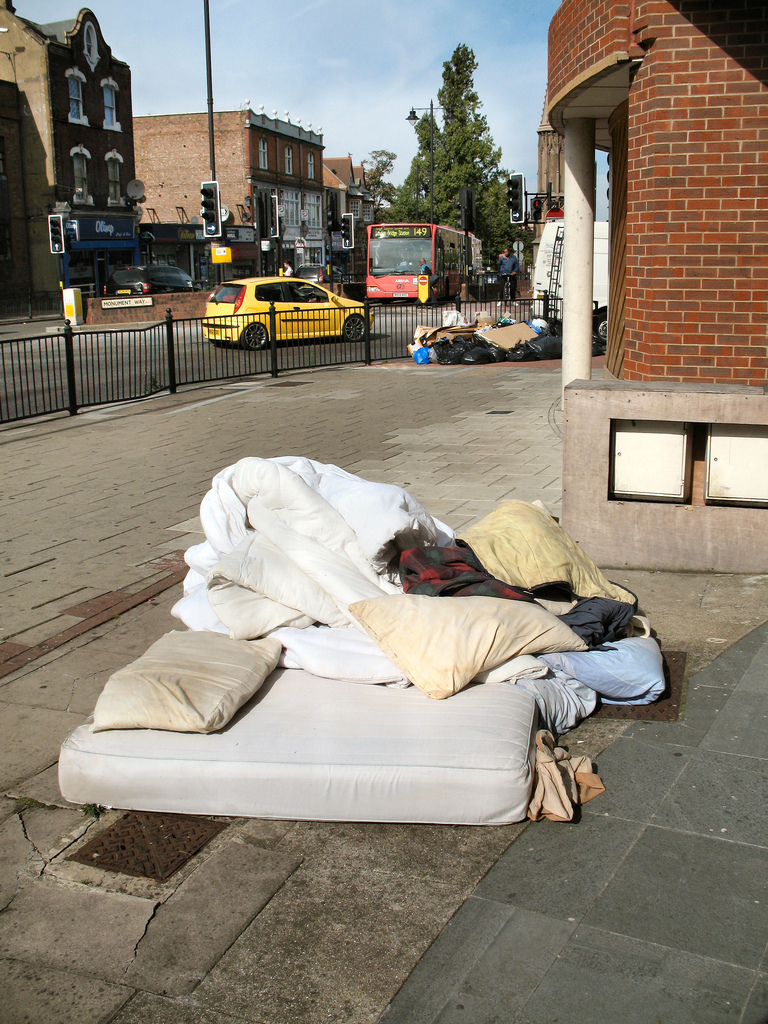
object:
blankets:
[190, 443, 401, 586]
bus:
[359, 208, 465, 328]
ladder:
[542, 224, 572, 330]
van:
[507, 191, 611, 326]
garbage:
[531, 309, 550, 340]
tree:
[444, 32, 514, 276]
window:
[65, 60, 87, 128]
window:
[85, 20, 99, 64]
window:
[71, 140, 90, 208]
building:
[0, 8, 167, 320]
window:
[258, 126, 268, 181]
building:
[134, 99, 325, 274]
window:
[307, 150, 316, 185]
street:
[8, 245, 483, 402]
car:
[190, 271, 396, 358]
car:
[113, 254, 208, 295]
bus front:
[367, 213, 437, 299]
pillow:
[77, 621, 287, 742]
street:
[0, 400, 758, 1022]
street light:
[194, 172, 227, 251]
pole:
[198, 5, 228, 180]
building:
[536, 5, 765, 407]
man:
[492, 243, 524, 311]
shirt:
[480, 271, 496, 290]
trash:
[483, 315, 535, 351]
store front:
[39, 14, 146, 318]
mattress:
[31, 600, 592, 847]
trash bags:
[444, 311, 472, 330]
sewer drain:
[38, 792, 255, 896]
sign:
[97, 295, 154, 312]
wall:
[76, 287, 210, 322]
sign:
[418, 269, 429, 304]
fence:
[2, 290, 548, 408]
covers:
[568, 627, 670, 702]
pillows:
[359, 585, 595, 694]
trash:
[59, 454, 669, 826]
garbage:
[406, 310, 440, 364]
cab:
[292, 280, 323, 305]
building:
[326, 142, 371, 271]